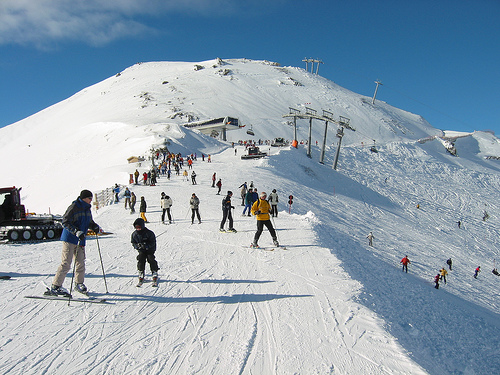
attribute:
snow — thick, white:
[61, 101, 278, 331]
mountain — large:
[4, 54, 489, 373]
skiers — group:
[124, 150, 278, 233]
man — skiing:
[56, 177, 91, 289]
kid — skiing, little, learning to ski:
[128, 204, 167, 289]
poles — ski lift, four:
[278, 105, 349, 169]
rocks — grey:
[195, 60, 301, 83]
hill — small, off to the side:
[441, 126, 499, 161]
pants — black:
[255, 216, 277, 245]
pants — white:
[52, 240, 88, 290]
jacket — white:
[159, 196, 175, 208]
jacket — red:
[400, 254, 412, 265]